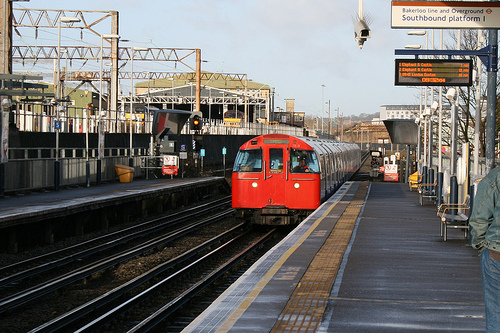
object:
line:
[135, 199, 182, 309]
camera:
[350, 16, 370, 51]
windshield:
[236, 147, 319, 174]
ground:
[167, 173, 498, 330]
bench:
[436, 193, 471, 241]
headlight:
[293, 182, 300, 189]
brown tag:
[488, 250, 498, 258]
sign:
[396, 59, 468, 83]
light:
[189, 110, 203, 130]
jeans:
[471, 244, 499, 331]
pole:
[482, 27, 499, 177]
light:
[251, 181, 258, 187]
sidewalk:
[351, 169, 491, 331]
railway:
[2, 171, 344, 333]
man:
[468, 137, 500, 332]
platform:
[180, 172, 497, 329]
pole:
[192, 121, 198, 178]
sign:
[391, 0, 500, 30]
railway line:
[2, 176, 301, 331]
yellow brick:
[275, 189, 352, 333]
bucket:
[115, 163, 135, 183]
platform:
[4, 160, 236, 241]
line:
[211, 179, 354, 331]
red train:
[230, 133, 364, 227]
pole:
[195, 49, 202, 113]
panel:
[379, 115, 430, 141]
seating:
[418, 171, 442, 207]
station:
[0, 0, 500, 333]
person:
[292, 153, 313, 173]